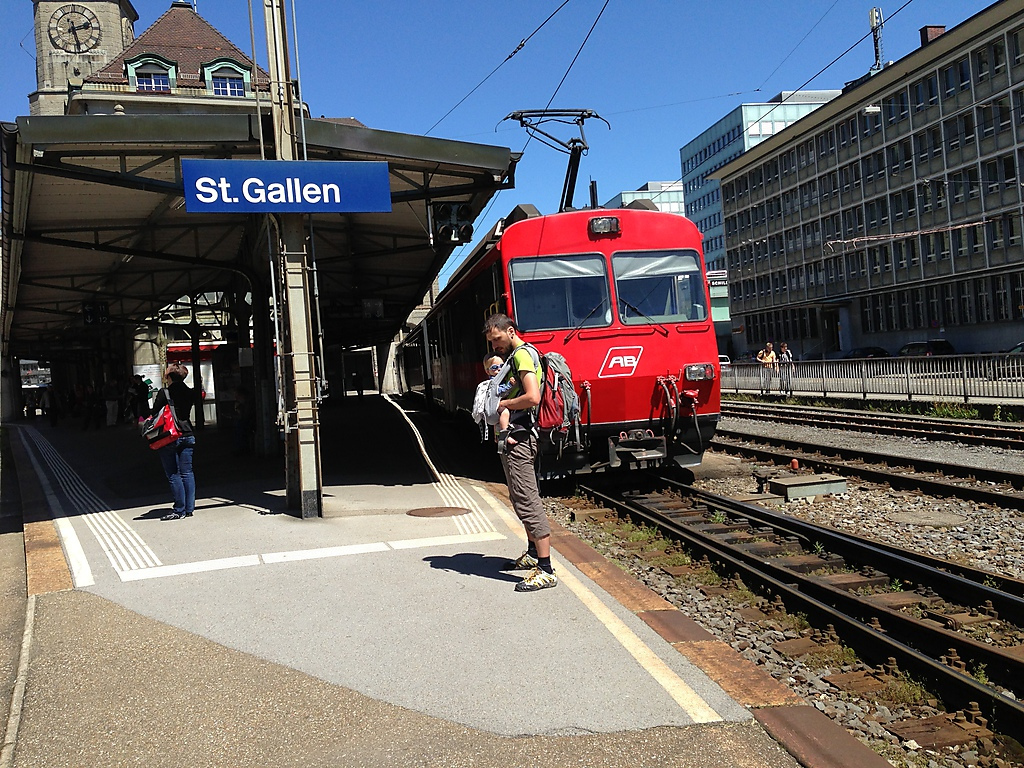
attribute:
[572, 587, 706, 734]
line — yellow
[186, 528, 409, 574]
lines — white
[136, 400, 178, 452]
bag — red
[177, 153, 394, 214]
sign — blue, white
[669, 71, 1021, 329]
building — side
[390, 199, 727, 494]
train — parked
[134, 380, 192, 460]
woman's handbag — red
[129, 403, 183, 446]
handbag — large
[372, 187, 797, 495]
train — parked, red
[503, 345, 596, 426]
back — mans